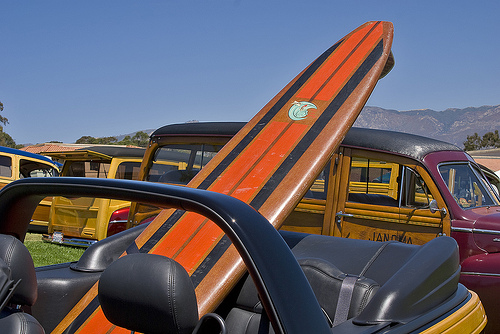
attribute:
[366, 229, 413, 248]
writing — black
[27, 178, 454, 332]
car — black 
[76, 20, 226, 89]
sky — blue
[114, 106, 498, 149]
mountain — gray 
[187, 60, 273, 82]
clouds — white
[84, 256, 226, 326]
headrest — black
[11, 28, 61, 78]
clouds — white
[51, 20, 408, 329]
surf board — black 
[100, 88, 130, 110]
sky — blue 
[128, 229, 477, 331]
car — yellow, black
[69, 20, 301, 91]
sky — clear, blue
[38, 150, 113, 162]
glass — open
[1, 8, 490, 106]
sky — blue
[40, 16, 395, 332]
surfboard — black, orange